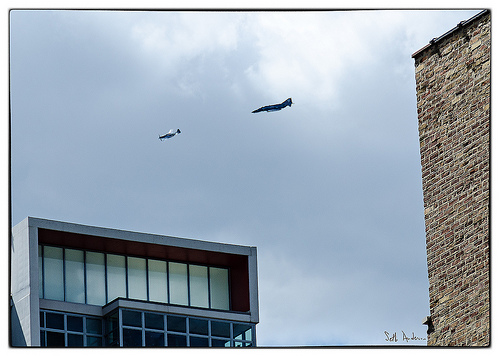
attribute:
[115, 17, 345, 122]
clouds — white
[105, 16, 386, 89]
cloud — white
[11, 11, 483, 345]
sky — blue